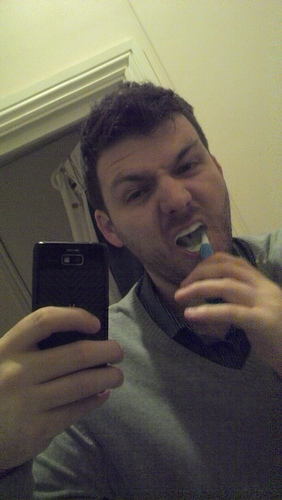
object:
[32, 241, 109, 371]
phone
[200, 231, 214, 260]
toothbrush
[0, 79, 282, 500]
man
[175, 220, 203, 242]
teeth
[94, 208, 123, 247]
ear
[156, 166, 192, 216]
nose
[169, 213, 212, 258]
mouth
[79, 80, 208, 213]
hair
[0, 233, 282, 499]
sweater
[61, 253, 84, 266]
camera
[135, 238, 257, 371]
shirt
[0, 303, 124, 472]
hand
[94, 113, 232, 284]
face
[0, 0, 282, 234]
wall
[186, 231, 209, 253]
foam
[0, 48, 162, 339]
door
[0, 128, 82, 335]
doorway